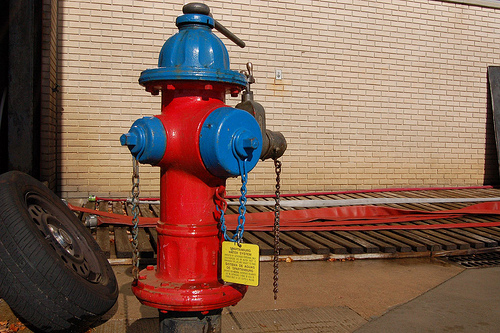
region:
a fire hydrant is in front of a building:
[112, 1, 287, 331]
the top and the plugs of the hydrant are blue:
[124, 12, 264, 178]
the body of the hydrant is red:
[136, 81, 249, 310]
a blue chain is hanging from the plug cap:
[214, 135, 253, 249]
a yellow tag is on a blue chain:
[218, 225, 263, 286]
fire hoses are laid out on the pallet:
[69, 184, 499, 244]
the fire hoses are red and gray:
[74, 179, 499, 264]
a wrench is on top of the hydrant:
[182, 1, 249, 51]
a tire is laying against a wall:
[3, 175, 120, 330]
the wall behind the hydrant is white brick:
[69, 0, 493, 187]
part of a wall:
[372, 88, 429, 155]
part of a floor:
[301, 272, 344, 303]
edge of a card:
[243, 253, 262, 290]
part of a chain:
[251, 235, 291, 299]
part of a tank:
[168, 223, 193, 260]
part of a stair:
[353, 233, 391, 258]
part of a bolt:
[236, 135, 267, 164]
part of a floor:
[318, 282, 354, 321]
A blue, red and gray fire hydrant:
[93, 2, 300, 317]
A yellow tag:
[215, 230, 268, 295]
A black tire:
[4, 135, 116, 330]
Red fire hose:
[286, 200, 496, 235]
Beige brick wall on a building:
[286, 4, 473, 167]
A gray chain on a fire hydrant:
[268, 159, 287, 306]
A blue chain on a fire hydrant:
[235, 176, 255, 236]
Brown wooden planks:
[282, 230, 499, 252]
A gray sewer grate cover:
[438, 251, 498, 278]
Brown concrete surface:
[280, 265, 412, 301]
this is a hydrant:
[101, 1, 276, 312]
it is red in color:
[161, 204, 210, 294]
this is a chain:
[266, 161, 291, 296]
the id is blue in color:
[175, 22, 220, 75]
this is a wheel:
[11, 192, 89, 300]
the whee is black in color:
[1, 211, 80, 312]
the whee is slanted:
[0, 202, 87, 307]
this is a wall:
[318, 23, 453, 160]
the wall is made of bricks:
[348, 25, 457, 154]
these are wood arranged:
[403, 218, 451, 250]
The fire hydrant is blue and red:
[108, 5, 297, 322]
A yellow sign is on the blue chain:
[218, 231, 268, 296]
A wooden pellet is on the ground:
[85, 179, 492, 258]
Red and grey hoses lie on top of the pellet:
[70, 176, 489, 234]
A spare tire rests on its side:
[15, 167, 136, 319]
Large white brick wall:
[68, 9, 486, 183]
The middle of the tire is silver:
[26, 177, 106, 301]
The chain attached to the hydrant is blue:
[196, 144, 264, 257]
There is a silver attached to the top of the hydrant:
[148, 2, 292, 101]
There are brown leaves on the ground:
[276, 249, 380, 272]